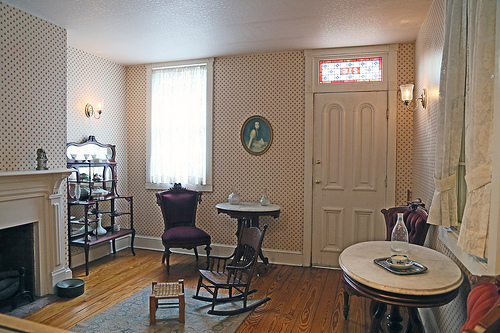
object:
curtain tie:
[424, 0, 462, 227]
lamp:
[260, 188, 270, 206]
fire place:
[0, 168, 77, 314]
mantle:
[0, 165, 75, 175]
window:
[316, 59, 385, 85]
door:
[307, 89, 392, 266]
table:
[338, 240, 464, 331]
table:
[214, 201, 281, 266]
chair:
[155, 181, 214, 276]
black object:
[53, 276, 84, 299]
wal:
[123, 50, 315, 277]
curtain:
[431, 0, 499, 275]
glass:
[319, 55, 384, 85]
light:
[398, 80, 427, 108]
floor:
[103, 247, 155, 281]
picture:
[238, 115, 273, 155]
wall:
[125, 49, 305, 252]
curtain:
[149, 65, 207, 185]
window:
[139, 60, 222, 197]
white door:
[313, 92, 385, 271]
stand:
[148, 279, 186, 322]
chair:
[192, 217, 274, 319]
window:
[452, 23, 485, 170]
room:
[0, 0, 499, 333]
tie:
[455, 0, 499, 260]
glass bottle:
[386, 212, 414, 272]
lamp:
[82, 96, 106, 120]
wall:
[72, 59, 132, 261]